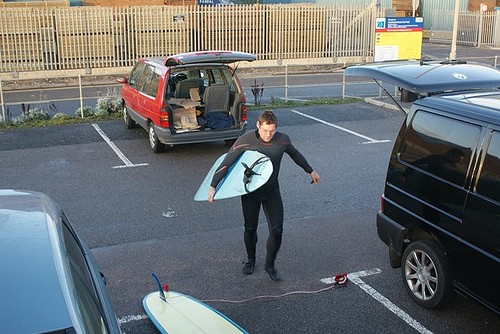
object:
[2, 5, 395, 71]
fence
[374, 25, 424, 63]
yellow sign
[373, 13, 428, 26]
blue banners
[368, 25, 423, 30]
red banners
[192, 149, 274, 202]
surfboard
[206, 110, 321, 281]
man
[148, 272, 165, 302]
fin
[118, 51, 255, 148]
van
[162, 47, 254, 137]
hatchback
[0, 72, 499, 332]
parking lot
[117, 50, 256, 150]
red van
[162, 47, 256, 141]
trunk door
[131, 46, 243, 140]
car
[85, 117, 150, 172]
line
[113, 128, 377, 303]
asphalt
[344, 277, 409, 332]
line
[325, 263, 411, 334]
asphalt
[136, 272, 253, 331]
surfboard